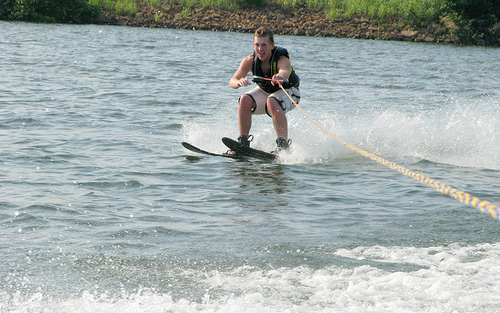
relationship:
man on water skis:
[217, 23, 305, 163] [177, 132, 278, 167]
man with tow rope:
[217, 23, 305, 163] [279, 83, 484, 213]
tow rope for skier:
[279, 83, 484, 213] [223, 24, 305, 158]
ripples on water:
[20, 105, 114, 142] [6, 28, 484, 307]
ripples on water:
[0, 21, 500, 312] [6, 28, 484, 307]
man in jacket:
[222, 27, 301, 161] [243, 50, 303, 94]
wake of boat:
[354, 257, 480, 309] [483, 201, 484, 202]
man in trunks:
[222, 27, 301, 161] [240, 81, 304, 115]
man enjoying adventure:
[222, 27, 301, 161] [5, 20, 484, 305]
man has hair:
[222, 27, 301, 161] [254, 26, 274, 39]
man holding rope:
[222, 27, 301, 161] [282, 82, 484, 222]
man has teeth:
[222, 27, 301, 161] [255, 53, 267, 60]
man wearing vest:
[222, 27, 301, 161] [243, 45, 302, 93]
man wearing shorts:
[222, 27, 301, 161] [239, 82, 304, 114]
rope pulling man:
[282, 82, 484, 222] [222, 27, 301, 161]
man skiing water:
[222, 27, 301, 161] [0, 20, 500, 313]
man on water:
[222, 27, 301, 161] [19, 160, 458, 292]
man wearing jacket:
[222, 27, 301, 161] [244, 51, 302, 98]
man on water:
[222, 27, 301, 161] [6, 28, 484, 307]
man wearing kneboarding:
[222, 27, 301, 161] [183, 94, 293, 175]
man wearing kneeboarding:
[222, 27, 301, 161] [179, 79, 310, 165]